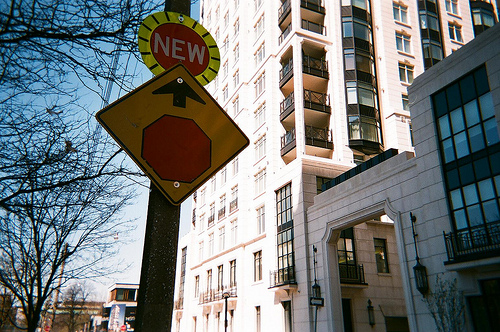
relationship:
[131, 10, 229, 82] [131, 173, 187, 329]
sign on pole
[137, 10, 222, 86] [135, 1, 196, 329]
sign on pole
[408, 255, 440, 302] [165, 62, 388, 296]
light on wall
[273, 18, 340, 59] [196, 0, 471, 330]
balcony of building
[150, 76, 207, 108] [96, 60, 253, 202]
arrow on sign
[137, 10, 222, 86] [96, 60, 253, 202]
sign above sign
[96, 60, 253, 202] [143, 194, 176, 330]
sign on pole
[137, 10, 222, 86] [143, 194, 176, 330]
sign on pole